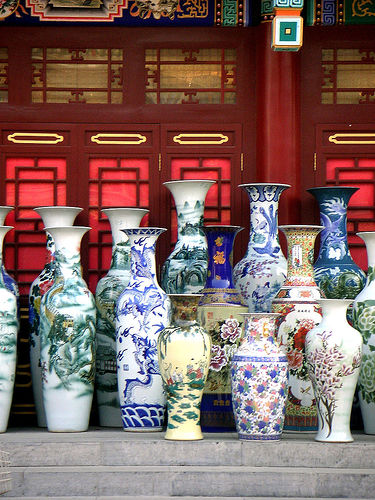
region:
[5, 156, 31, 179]
red section of door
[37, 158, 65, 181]
red section of door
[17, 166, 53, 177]
red section of door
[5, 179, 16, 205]
red section of door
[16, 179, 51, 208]
red section of door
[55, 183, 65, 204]
red section of door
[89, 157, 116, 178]
red section of door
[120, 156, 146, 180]
red section of door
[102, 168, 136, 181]
red section of door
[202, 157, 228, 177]
red section of door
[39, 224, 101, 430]
green and white vase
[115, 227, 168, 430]
white and blue vase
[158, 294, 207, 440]
green and ivory vase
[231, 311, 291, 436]
pink and blue floral vase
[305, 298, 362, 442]
pink and white vase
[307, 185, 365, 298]
blue white and green vase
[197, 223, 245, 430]
blue and tan vase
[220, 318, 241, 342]
white and pink flower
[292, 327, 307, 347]
red rose on vase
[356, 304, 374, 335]
green flower on vase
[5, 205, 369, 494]
vessels are a t a disply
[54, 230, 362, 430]
vases are used to store flowers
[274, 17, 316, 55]
the socket is white green in color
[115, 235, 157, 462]
the vase is blue flowerd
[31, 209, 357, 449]
the vases are a traditional work of art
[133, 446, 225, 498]
the floor is made of concrete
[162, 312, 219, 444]
the vase is flower green in color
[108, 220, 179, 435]
a blue and white Chinese vase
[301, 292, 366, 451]
a white Chinese vase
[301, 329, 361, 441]
flowers decorations on vase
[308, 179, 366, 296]
a blue and green Chinese vase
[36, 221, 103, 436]
a blue and white Chinese vase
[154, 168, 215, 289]
a blue and white Chinese vase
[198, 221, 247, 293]
a blue Chinese vase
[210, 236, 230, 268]
orange decorations on neck of vase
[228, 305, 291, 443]
vase decorated with blue flowers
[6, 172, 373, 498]
vases on gray surface